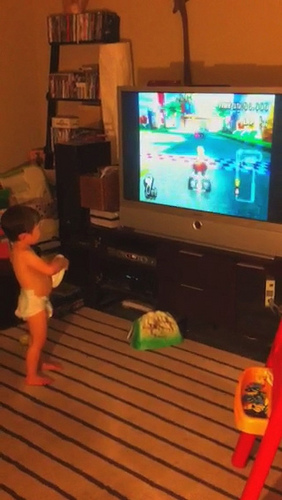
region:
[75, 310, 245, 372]
black stripe on carpet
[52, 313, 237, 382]
black stripe on carpet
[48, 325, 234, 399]
black stripe on carpet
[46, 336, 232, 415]
black stripe on carpet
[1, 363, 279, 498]
black stripe on carpet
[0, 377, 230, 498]
black stripe on carpet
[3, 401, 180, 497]
black stripe on carpet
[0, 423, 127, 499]
black stripe on carpet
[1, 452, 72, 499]
black stripe on carpet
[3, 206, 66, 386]
the kid in pamper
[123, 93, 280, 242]
a PC game on the screen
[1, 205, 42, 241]
the hair is black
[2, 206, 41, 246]
the head of the kid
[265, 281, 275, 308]
a white electric plug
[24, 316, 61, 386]
the legs of the kid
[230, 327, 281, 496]
this object is red and yellow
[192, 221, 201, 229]
the TV on/off button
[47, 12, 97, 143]
looks like books and DVDs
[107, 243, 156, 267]
this is an electronic device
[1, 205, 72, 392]
small child holding wii remote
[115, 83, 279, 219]
television screen showing game in progress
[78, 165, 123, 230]
box sitting upon stack of books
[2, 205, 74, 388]
child wearing a diaper playing games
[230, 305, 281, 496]
toddler toy containing magnets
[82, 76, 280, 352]
television set on entertainment shelf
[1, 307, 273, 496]
stripped rug on floor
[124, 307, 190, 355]
toddler toy on stripped rug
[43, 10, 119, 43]
movies and games on the shelf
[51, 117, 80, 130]
box ontop of movies on the shelf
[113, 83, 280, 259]
TV screen displaying video game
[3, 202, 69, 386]
dark haired Caucasian toddler standing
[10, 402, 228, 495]
light colored rug with dark stripes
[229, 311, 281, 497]
side view of red plastic easel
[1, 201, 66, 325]
toddler wearing white diaper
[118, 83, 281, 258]
large screened silver TV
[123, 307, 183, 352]
green and white plastic toy on floor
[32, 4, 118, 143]
several books on bookshelf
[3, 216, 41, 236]
Kid has dark hair.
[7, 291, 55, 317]
Kid wearing white diaper.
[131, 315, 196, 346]
Green bag laying on floor.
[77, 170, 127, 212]
Brown box near television.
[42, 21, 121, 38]
DVD's on top shelf.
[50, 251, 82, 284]
Child holding white steering wheel.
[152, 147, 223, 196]
Television is turned on.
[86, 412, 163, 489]
Brown stripes on floor.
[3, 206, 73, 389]
baby in diapers playing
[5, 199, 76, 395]
baby in diapers playing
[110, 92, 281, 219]
screen of the television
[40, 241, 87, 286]
arm of the kid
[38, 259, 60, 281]
elbow of the kid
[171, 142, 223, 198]
character on the screen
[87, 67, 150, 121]
corner of the screen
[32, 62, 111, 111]
items on the shelf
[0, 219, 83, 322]
kid in a diaper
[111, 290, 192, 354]
item under the television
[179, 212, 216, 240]
round shape on the object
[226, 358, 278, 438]
yellow tray holding toys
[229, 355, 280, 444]
yellow tray holding toys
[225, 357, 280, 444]
yellow tray holding toys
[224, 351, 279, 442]
yellow tray holding toys